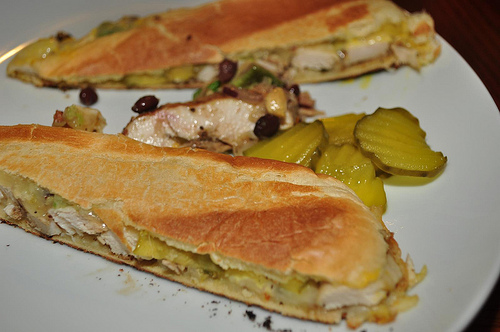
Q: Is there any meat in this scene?
A: Yes, there is meat.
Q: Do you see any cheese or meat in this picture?
A: Yes, there is meat.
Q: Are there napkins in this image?
A: No, there are no napkins.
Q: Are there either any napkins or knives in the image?
A: No, there are no napkins or knives.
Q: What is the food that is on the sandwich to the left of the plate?
A: The food is meat.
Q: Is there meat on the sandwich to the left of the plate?
A: Yes, there is meat on the sandwich.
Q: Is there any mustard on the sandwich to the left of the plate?
A: No, there is meat on the sandwich.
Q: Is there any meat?
A: Yes, there is meat.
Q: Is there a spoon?
A: No, there are no spoons.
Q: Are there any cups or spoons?
A: No, there are no spoons or cups.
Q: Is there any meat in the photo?
A: Yes, there is meat.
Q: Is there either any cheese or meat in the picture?
A: Yes, there is meat.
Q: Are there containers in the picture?
A: No, there are no containers.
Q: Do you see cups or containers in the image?
A: No, there are no containers or cups.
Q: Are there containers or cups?
A: No, there are no containers or cups.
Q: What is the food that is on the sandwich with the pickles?
A: The food is meat.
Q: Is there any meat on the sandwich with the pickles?
A: Yes, there is meat on the sandwich.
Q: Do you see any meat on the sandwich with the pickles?
A: Yes, there is meat on the sandwich.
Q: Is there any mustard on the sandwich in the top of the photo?
A: No, there is meat on the sandwich.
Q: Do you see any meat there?
A: Yes, there is meat.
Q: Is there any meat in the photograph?
A: Yes, there is meat.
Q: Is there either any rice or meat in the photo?
A: Yes, there is meat.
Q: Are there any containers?
A: No, there are no containers.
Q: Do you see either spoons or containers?
A: No, there are no containers or spoons.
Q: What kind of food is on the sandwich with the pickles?
A: The food is meat.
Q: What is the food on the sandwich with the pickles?
A: The food is meat.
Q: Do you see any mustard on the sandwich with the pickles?
A: No, there is meat on the sandwich.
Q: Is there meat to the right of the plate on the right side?
A: No, the meat is to the left of the plate.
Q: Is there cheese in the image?
A: Yes, there is cheese.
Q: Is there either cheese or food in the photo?
A: Yes, there is cheese.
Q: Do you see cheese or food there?
A: Yes, there is cheese.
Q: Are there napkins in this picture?
A: No, there are no napkins.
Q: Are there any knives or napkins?
A: No, there are no napkins or knives.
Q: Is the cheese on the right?
A: Yes, the cheese is on the right of the image.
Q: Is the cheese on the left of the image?
A: No, the cheese is on the right of the image.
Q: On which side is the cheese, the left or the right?
A: The cheese is on the right of the image.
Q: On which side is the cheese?
A: The cheese is on the right of the image.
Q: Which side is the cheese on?
A: The cheese is on the right of the image.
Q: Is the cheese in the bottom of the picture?
A: Yes, the cheese is in the bottom of the image.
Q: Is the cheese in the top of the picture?
A: No, the cheese is in the bottom of the image.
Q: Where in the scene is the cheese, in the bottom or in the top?
A: The cheese is in the bottom of the image.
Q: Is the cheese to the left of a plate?
A: Yes, the cheese is to the left of a plate.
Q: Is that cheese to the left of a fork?
A: No, the cheese is to the left of a plate.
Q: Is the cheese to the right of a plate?
A: No, the cheese is to the left of a plate.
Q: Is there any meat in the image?
A: Yes, there is meat.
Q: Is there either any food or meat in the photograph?
A: Yes, there is meat.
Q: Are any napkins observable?
A: No, there are no napkins.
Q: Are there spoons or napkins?
A: No, there are no napkins or spoons.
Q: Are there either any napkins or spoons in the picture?
A: No, there are no napkins or spoons.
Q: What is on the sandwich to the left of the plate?
A: The meat is on the sandwich.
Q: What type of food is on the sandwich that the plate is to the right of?
A: The food is meat.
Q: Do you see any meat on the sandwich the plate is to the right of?
A: Yes, there is meat on the sandwich.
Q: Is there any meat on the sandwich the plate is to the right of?
A: Yes, there is meat on the sandwich.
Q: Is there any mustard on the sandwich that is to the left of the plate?
A: No, there is meat on the sandwich.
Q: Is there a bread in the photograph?
A: Yes, there is a bread.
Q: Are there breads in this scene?
A: Yes, there is a bread.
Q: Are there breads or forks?
A: Yes, there is a bread.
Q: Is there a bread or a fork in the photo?
A: Yes, there is a bread.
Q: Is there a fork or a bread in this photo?
A: Yes, there is a bread.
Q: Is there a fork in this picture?
A: No, there are no forks.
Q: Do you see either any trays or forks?
A: No, there are no forks or trays.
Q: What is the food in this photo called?
A: The food is a bread.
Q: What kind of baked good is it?
A: The food is a bread.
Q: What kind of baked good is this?
A: That is a bread.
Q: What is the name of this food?
A: That is a bread.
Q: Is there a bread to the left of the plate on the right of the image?
A: Yes, there is a bread to the left of the plate.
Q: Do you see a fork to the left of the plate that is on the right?
A: No, there is a bread to the left of the plate.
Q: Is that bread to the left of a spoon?
A: No, the bread is to the left of the plate.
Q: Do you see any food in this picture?
A: Yes, there is food.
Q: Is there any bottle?
A: No, there are no bottles.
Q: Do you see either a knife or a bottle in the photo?
A: No, there are no bottles or knives.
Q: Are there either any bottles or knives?
A: No, there are no bottles or knives.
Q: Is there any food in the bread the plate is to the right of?
A: Yes, there is food in the bread.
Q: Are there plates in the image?
A: Yes, there is a plate.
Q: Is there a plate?
A: Yes, there is a plate.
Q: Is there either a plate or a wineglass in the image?
A: Yes, there is a plate.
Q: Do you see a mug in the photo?
A: No, there are no mugs.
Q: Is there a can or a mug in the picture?
A: No, there are no mugs or cans.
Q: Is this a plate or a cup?
A: This is a plate.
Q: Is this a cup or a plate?
A: This is a plate.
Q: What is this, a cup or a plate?
A: This is a plate.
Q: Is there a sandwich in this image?
A: Yes, there is a sandwich.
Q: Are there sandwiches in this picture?
A: Yes, there is a sandwich.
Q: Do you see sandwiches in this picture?
A: Yes, there is a sandwich.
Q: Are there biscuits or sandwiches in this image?
A: Yes, there is a sandwich.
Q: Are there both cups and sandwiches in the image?
A: No, there is a sandwich but no cups.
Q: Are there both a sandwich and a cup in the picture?
A: No, there is a sandwich but no cups.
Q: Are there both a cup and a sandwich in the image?
A: No, there is a sandwich but no cups.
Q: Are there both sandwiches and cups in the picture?
A: No, there is a sandwich but no cups.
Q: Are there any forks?
A: No, there are no forks.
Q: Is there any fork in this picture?
A: No, there are no forks.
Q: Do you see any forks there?
A: No, there are no forks.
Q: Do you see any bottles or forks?
A: No, there are no forks or bottles.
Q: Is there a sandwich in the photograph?
A: Yes, there is a sandwich.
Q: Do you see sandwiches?
A: Yes, there is a sandwich.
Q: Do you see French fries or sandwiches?
A: Yes, there is a sandwich.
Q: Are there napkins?
A: No, there are no napkins.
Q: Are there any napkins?
A: No, there are no napkins.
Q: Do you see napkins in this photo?
A: No, there are no napkins.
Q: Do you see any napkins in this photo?
A: No, there are no napkins.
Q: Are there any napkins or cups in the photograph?
A: No, there are no napkins or cups.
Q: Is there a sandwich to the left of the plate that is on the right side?
A: Yes, there is a sandwich to the left of the plate.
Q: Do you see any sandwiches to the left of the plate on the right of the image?
A: Yes, there is a sandwich to the left of the plate.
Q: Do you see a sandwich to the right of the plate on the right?
A: No, the sandwich is to the left of the plate.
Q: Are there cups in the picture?
A: No, there are no cups.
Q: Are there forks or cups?
A: No, there are no cups or forks.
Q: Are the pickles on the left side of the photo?
A: Yes, the pickles are on the left of the image.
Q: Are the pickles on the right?
A: No, the pickles are on the left of the image.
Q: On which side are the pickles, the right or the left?
A: The pickles are on the left of the image.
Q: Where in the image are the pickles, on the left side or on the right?
A: The pickles are on the left of the image.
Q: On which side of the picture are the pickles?
A: The pickles are on the left of the image.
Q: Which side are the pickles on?
A: The pickles are on the left of the image.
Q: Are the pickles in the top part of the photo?
A: Yes, the pickles are in the top of the image.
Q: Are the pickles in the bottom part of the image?
A: No, the pickles are in the top of the image.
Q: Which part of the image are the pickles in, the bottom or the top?
A: The pickles are in the top of the image.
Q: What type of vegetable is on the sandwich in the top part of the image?
A: The vegetables are pickles.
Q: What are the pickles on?
A: The pickles are on the sandwich.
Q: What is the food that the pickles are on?
A: The food is a sandwich.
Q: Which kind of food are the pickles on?
A: The pickles are on the sandwich.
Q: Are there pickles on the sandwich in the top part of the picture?
A: Yes, there are pickles on the sandwich.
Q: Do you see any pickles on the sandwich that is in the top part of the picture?
A: Yes, there are pickles on the sandwich.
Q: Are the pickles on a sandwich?
A: Yes, the pickles are on a sandwich.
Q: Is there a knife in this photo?
A: No, there are no knives.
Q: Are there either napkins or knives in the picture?
A: No, there are no knives or napkins.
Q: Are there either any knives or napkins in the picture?
A: No, there are no knives or napkins.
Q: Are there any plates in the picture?
A: Yes, there is a plate.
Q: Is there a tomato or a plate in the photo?
A: Yes, there is a plate.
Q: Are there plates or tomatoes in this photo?
A: Yes, there is a plate.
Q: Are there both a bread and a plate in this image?
A: Yes, there are both a plate and a bread.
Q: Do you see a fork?
A: No, there are no forks.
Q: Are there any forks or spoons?
A: No, there are no forks or spoons.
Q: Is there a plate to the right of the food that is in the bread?
A: Yes, there is a plate to the right of the food.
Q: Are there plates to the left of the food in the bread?
A: No, the plate is to the right of the food.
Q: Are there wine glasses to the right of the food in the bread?
A: No, there is a plate to the right of the food.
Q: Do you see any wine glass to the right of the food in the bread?
A: No, there is a plate to the right of the food.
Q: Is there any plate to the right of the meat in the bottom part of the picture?
A: Yes, there is a plate to the right of the meat.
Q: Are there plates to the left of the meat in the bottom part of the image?
A: No, the plate is to the right of the meat.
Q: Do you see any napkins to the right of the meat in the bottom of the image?
A: No, there is a plate to the right of the meat.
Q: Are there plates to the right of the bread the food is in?
A: Yes, there is a plate to the right of the bread.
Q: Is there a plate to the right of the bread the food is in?
A: Yes, there is a plate to the right of the bread.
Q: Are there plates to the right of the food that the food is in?
A: Yes, there is a plate to the right of the bread.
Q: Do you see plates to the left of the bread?
A: No, the plate is to the right of the bread.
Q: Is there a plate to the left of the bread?
A: No, the plate is to the right of the bread.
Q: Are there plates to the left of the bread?
A: No, the plate is to the right of the bread.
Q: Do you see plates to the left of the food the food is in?
A: No, the plate is to the right of the bread.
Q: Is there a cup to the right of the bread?
A: No, there is a plate to the right of the bread.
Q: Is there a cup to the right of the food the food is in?
A: No, there is a plate to the right of the bread.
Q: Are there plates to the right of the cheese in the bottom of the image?
A: Yes, there is a plate to the right of the cheese.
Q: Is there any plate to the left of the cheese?
A: No, the plate is to the right of the cheese.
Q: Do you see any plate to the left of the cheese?
A: No, the plate is to the right of the cheese.